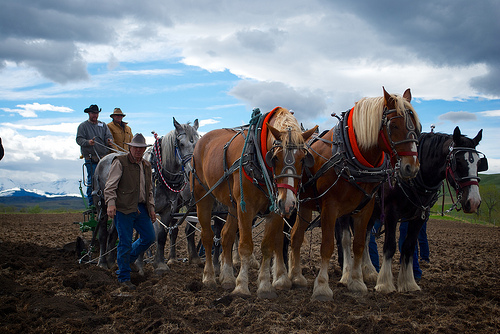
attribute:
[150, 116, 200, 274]
horse — gray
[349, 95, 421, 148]
mane — blonde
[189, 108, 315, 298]
horse — brown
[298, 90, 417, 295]
horse — brown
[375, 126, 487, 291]
horse — black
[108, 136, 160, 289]
man — walking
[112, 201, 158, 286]
jeans — blue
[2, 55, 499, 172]
sky — blue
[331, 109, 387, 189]
bridle — red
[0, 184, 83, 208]
mountains — distant